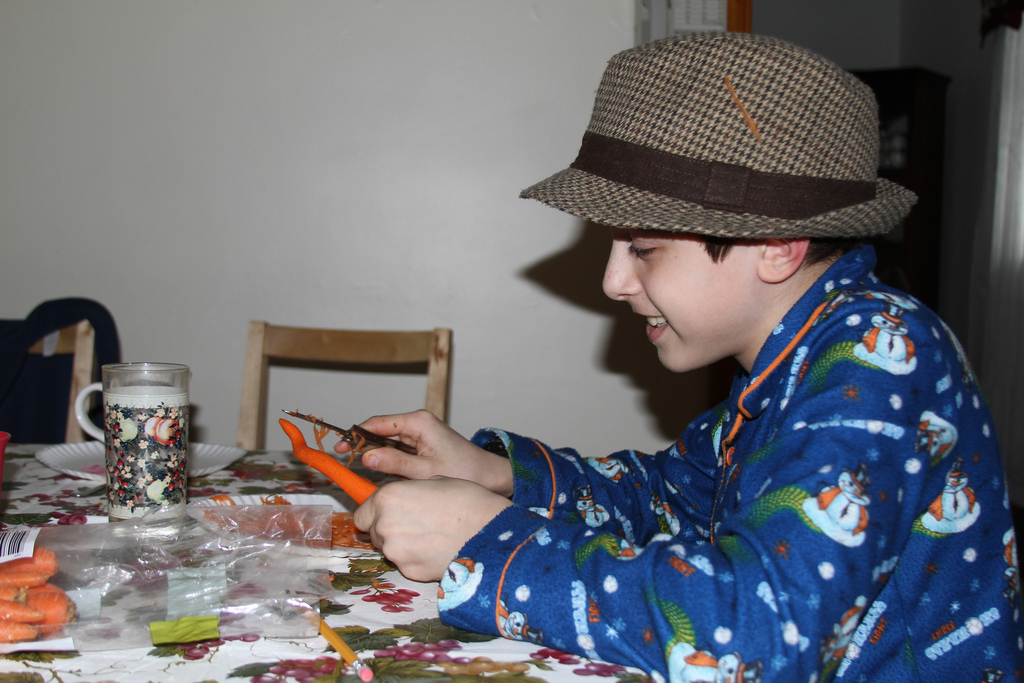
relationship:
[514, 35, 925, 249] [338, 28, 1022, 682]
hat on boy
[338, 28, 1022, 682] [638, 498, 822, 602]
boy wearing pajamas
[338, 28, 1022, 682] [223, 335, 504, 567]
boy shaving carrot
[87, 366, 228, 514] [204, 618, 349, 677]
glass on table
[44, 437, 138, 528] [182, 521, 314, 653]
plate on table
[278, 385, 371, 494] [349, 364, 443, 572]
carrot in hands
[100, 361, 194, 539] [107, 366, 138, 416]
glass filled with milk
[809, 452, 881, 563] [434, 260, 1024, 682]
snow man on pajamas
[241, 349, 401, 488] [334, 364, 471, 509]
device in hand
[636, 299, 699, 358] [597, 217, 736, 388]
smile on face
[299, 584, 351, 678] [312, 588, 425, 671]
pencil on table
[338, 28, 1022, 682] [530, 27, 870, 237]
boy wearing hat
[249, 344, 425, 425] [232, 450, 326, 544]
chair pulled up to table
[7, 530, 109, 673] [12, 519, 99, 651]
bag filled with carrots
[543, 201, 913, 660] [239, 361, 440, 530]
boy peeling carrots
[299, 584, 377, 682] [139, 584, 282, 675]
pencil on table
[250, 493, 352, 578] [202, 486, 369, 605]
peeling in plate